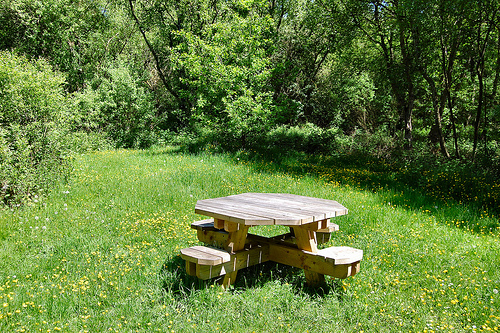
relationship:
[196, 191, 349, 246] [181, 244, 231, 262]
table with chair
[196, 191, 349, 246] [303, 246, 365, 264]
table with chair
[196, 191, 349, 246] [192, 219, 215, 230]
table with chair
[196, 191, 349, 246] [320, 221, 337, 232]
table with chair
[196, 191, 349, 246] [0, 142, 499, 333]
table on grass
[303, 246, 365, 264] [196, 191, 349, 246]
chair attached to table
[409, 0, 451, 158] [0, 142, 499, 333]
tree surrounds grass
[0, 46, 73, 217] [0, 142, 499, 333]
bush on grass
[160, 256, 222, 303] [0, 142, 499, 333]
shadow over grass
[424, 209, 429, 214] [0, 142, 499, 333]
flower on grass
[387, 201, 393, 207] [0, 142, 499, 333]
flower on grass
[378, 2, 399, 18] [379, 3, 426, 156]
branch of tree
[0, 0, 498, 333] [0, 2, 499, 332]
photo during daytime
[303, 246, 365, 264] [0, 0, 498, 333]
chair in photo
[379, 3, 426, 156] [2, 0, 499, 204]
tree in background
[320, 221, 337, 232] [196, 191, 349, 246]
chair connected to table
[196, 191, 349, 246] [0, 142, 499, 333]
table in grass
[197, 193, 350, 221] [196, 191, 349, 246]
top of table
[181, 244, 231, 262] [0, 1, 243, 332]
seat on left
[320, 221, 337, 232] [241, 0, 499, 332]
chair on right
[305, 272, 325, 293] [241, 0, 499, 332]
leg on right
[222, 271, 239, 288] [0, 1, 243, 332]
leg on left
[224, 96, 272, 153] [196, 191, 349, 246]
brush behind table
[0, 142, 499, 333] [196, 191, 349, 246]
grass surrounding table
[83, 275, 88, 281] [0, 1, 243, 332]
flower in left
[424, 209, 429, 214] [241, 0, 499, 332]
flower on right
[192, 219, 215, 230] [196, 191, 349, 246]
chair of table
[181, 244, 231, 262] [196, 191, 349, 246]
chair of table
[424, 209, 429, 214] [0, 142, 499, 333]
flower in grass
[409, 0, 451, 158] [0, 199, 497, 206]
tree in forest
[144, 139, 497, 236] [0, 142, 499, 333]
shadow on grass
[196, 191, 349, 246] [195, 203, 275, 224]
table has board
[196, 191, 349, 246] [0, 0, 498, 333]
table in picture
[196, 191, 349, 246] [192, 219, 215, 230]
table has chair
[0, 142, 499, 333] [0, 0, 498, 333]
grass in photo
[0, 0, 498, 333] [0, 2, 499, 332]
photo in daytime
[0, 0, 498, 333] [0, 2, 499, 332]
photo was taken on daytime